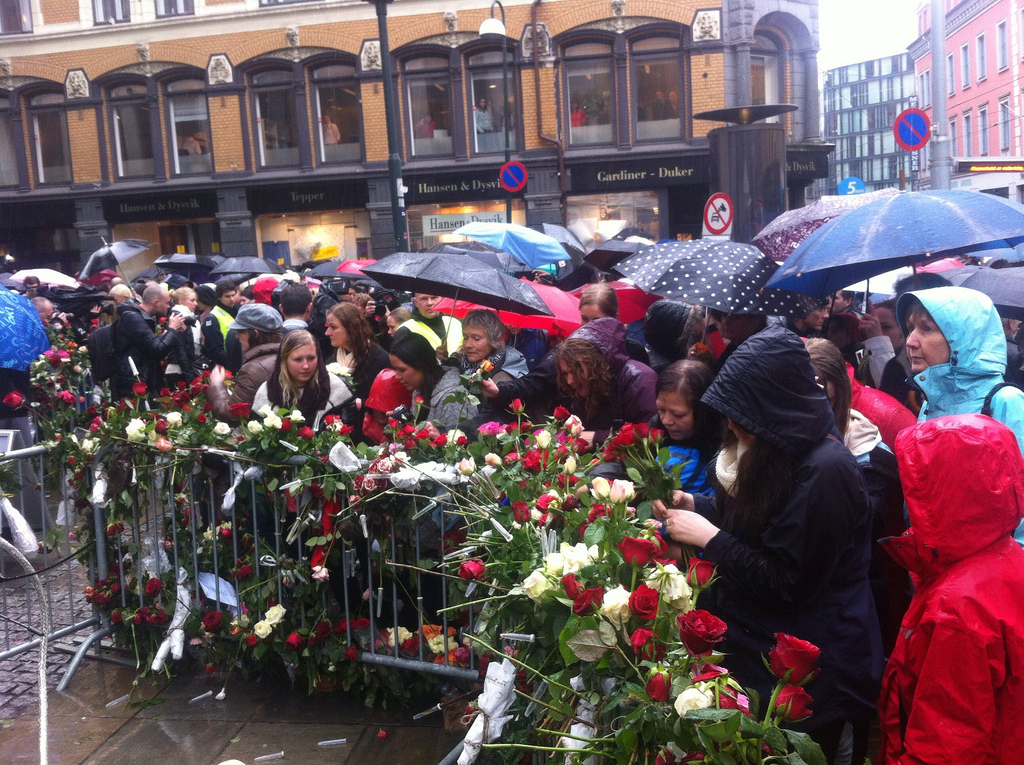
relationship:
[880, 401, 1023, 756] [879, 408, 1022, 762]
person wearing coat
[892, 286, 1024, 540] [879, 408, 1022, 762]
woman wearing coat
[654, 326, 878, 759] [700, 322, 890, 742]
woman in raincoat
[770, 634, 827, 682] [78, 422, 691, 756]
flower on railing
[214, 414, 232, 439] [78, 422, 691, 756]
rose on railing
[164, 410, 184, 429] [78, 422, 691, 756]
rose on railing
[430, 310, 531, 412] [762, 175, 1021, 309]
person holding umbrella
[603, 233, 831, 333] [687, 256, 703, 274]
umbrella with dots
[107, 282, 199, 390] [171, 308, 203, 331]
man holding camera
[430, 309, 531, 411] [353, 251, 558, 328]
person holding umbrella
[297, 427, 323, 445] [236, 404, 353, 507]
flower on plant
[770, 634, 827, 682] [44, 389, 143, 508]
flower on plant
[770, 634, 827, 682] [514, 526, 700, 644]
flower on plant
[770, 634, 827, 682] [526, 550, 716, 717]
flower on plant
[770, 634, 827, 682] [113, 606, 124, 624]
flower has flower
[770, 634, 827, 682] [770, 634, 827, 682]
flower with flower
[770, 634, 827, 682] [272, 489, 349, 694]
flower on plant